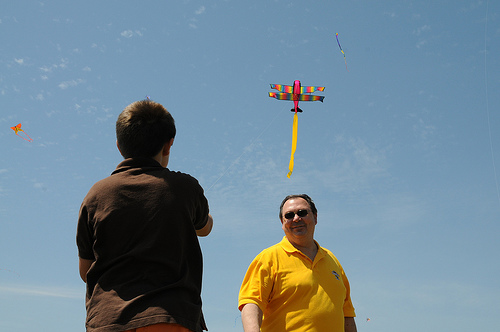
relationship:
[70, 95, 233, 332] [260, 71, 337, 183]
boy holding kite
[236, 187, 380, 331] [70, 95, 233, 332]
man near boy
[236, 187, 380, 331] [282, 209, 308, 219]
man has eyes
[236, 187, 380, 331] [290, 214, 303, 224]
man has nose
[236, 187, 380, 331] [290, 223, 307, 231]
man has mouth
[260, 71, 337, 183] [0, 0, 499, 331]
kite in sky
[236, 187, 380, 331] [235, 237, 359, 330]
man in shirt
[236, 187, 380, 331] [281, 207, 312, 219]
man in glasses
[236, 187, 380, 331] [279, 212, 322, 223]
man has ears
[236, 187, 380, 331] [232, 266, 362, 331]
man has arms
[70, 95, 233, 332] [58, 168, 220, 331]
boy wearing brown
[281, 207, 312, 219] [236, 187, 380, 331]
glasses on man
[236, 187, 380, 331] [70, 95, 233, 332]
man watching boy